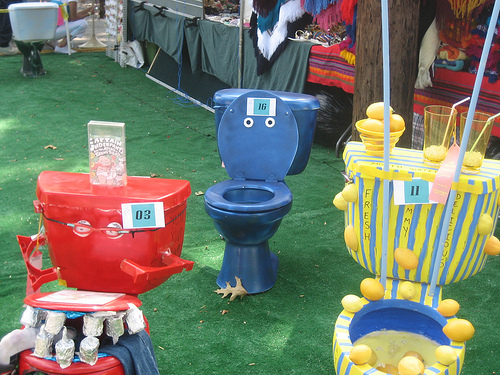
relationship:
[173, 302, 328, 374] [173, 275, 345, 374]
floor of floor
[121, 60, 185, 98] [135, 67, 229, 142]
part of line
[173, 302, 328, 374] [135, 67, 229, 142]
floor of line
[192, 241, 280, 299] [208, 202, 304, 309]
p of base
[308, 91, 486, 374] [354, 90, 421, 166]
toilet has lemons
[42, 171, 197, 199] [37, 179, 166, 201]
hard part surface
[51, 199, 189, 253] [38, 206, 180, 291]
part of tank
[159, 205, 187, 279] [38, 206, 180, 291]
side of tank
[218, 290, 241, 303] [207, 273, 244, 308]
edge of leaf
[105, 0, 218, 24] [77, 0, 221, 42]
part of board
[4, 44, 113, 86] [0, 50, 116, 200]
edge of field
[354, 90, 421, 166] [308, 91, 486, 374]
lemons on toilet